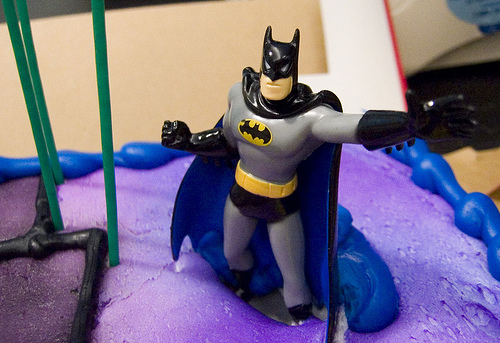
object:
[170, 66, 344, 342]
suit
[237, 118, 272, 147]
crest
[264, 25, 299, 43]
cape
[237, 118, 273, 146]
logo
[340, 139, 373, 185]
ground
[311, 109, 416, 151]
arm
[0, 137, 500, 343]
icing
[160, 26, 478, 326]
toy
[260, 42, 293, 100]
face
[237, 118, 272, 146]
symbol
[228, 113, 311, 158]
chest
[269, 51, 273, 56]
light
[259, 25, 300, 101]
head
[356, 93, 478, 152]
black gloves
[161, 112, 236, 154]
black gloves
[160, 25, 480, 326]
action figure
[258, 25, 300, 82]
face mask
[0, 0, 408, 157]
wall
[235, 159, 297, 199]
belt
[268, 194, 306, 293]
legs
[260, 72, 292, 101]
mask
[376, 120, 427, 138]
part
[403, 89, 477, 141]
hand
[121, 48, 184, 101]
part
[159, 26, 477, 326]
batman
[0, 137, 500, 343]
cake